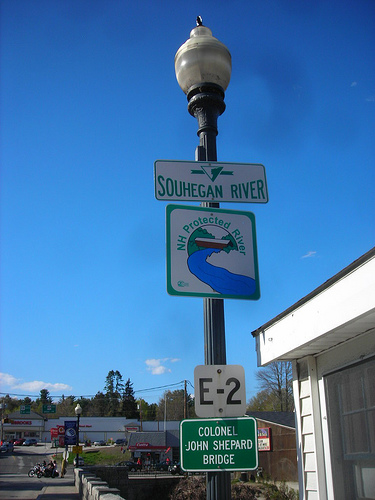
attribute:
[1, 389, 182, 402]
wires — for telephones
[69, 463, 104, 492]
wall — stone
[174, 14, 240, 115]
lamp — tall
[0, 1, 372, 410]
sky — clear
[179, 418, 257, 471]
sign — green, white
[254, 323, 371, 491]
building — white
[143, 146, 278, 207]
sign — white, green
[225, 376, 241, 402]
2 — black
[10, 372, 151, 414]
green trees — distant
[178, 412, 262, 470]
sign — green, white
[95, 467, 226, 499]
bridge — paved, road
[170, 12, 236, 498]
light post — large